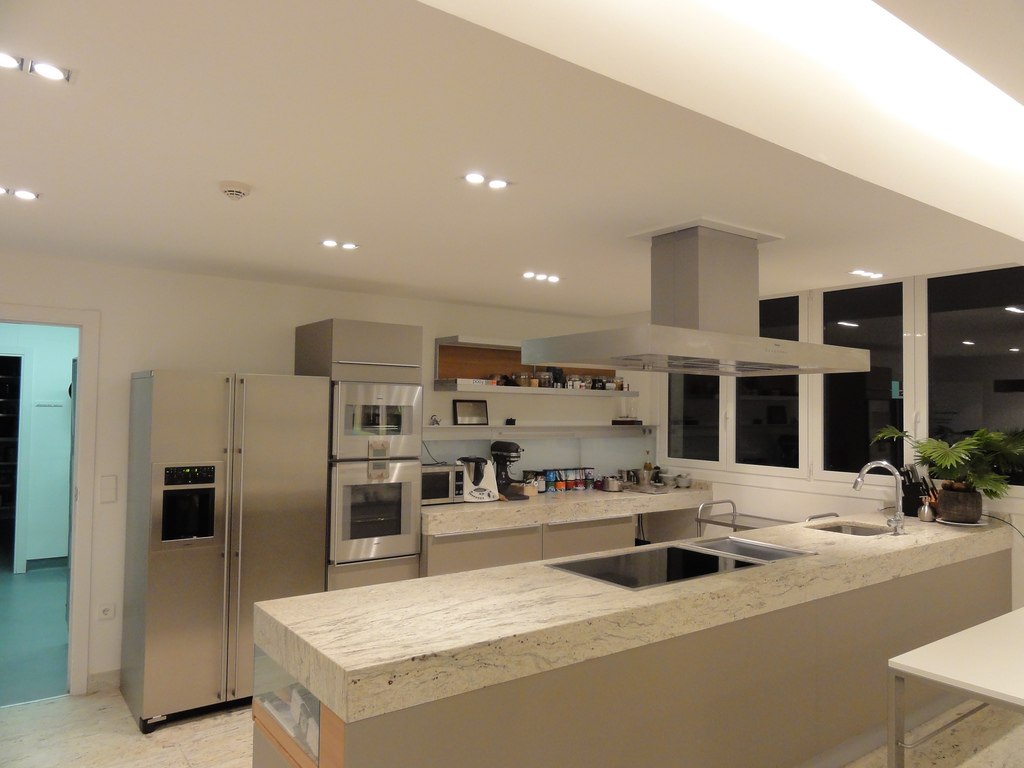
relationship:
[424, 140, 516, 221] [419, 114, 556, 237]
light on ceiling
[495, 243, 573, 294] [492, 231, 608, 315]
light on ceiling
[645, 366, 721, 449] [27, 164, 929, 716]
window in kitchen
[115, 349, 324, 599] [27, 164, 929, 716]
refrigerator in kitchen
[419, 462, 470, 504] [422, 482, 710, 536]
microwave on countertop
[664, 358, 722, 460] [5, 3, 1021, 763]
window on kitchen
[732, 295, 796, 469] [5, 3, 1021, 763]
window on kitchen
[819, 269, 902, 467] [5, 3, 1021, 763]
window on kitchen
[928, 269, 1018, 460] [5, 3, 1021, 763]
window on kitchen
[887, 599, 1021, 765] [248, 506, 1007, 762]
table to right of island